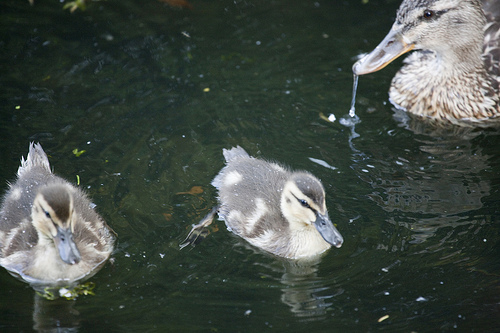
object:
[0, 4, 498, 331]
water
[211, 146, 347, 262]
duck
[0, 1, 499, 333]
lake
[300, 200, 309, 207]
eye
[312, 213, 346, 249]
bill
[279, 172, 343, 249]
head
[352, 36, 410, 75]
beak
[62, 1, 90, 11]
leaves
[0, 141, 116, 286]
ducks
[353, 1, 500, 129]
duck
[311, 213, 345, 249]
beak